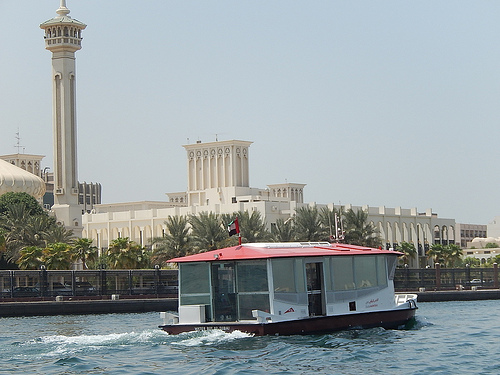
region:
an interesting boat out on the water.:
[75, 110, 460, 351]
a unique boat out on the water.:
[80, 85, 460, 340]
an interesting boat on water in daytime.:
[50, 85, 460, 335]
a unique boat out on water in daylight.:
[30, 65, 465, 355]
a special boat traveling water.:
[86, 131, 456, 351]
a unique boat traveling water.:
[26, 116, 466, 351]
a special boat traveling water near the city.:
[80, 72, 465, 357]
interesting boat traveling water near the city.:
[35, 100, 460, 345]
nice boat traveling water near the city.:
[47, 85, 477, 357]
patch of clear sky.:
[263, 30, 463, 155]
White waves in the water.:
[182, 327, 244, 347]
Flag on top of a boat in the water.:
[228, 215, 242, 246]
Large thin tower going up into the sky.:
[38, 0, 90, 292]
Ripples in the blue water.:
[442, 310, 472, 330]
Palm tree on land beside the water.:
[20, 239, 63, 297]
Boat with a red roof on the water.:
[156, 240, 421, 336]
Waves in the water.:
[51, 355, 88, 370]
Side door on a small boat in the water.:
[300, 260, 325, 315]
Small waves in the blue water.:
[435, 346, 480, 366]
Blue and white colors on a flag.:
[228, 219, 237, 237]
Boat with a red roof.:
[142, 225, 441, 332]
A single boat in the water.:
[130, 235, 443, 342]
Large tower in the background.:
[32, 0, 108, 247]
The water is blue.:
[1, 291, 492, 368]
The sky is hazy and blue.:
[0, 2, 488, 238]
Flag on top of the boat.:
[210, 217, 253, 252]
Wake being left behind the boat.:
[26, 321, 274, 356]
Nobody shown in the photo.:
[2, 47, 489, 361]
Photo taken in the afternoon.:
[11, 10, 479, 352]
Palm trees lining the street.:
[22, 188, 488, 286]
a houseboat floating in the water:
[151, 214, 422, 339]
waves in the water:
[57, 329, 251, 354]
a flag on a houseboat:
[227, 220, 243, 243]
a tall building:
[41, 1, 97, 269]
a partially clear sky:
[126, 41, 488, 142]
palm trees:
[31, 235, 144, 265]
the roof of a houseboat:
[164, 238, 403, 261]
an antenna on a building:
[11, 126, 25, 152]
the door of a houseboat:
[301, 263, 331, 314]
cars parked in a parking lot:
[11, 265, 168, 297]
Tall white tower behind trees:
[42, 0, 89, 235]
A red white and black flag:
[226, 208, 248, 254]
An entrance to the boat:
[209, 255, 245, 329]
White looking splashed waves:
[29, 328, 262, 351]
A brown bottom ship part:
[149, 305, 426, 340]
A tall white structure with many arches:
[77, 133, 479, 270]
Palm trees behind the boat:
[17, 236, 142, 296]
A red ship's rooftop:
[159, 230, 415, 262]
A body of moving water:
[2, 304, 491, 372]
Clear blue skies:
[0, 0, 496, 223]